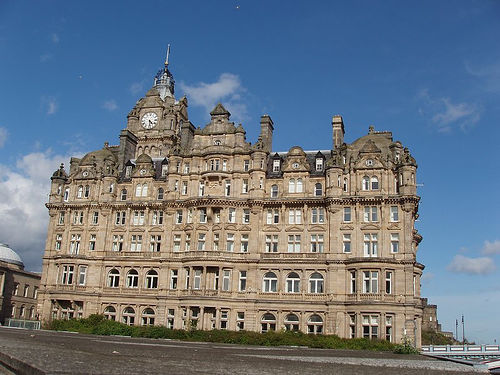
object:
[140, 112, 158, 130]
clock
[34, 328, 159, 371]
ground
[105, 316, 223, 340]
grass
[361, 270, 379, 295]
windows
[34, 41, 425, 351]
castle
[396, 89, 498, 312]
sky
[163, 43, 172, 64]
flag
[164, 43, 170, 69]
pole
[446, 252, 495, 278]
cloud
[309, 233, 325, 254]
window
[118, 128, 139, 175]
parapets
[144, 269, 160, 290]
windows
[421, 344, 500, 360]
bridge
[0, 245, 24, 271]
dome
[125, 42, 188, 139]
tower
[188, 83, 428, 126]
sky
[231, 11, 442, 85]
sky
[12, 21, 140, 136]
sky